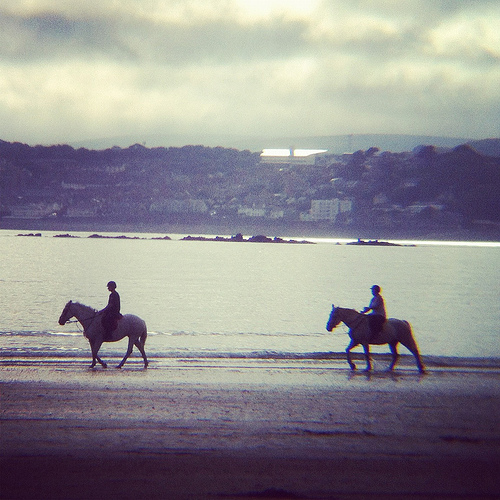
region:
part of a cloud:
[255, 29, 297, 74]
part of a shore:
[226, 365, 284, 423]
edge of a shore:
[228, 362, 286, 431]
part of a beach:
[191, 336, 271, 403]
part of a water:
[219, 290, 258, 322]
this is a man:
[366, 277, 384, 326]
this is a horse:
[121, 315, 141, 357]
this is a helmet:
[370, 282, 386, 294]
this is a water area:
[161, 244, 277, 321]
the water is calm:
[180, 266, 235, 321]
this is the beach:
[193, 374, 367, 491]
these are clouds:
[183, 24, 469, 123]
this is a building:
[261, 148, 314, 159]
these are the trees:
[421, 144, 469, 191]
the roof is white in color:
[266, 147, 293, 157]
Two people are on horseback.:
[55, 272, 451, 396]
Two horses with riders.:
[38, 270, 453, 396]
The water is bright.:
[166, 254, 283, 303]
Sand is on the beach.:
[190, 408, 353, 474]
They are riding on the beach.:
[49, 270, 459, 436]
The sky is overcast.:
[96, 63, 299, 123]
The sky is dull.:
[89, 57, 311, 126]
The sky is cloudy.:
[78, 58, 340, 123]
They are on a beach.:
[51, 270, 466, 432]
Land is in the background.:
[0, 129, 499, 281]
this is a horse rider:
[55, 280, 160, 364]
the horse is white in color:
[128, 317, 143, 339]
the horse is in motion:
[347, 323, 415, 377]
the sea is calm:
[201, 275, 292, 350]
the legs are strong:
[89, 344, 149, 369]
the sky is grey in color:
[204, 27, 351, 104]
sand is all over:
[149, 378, 331, 471]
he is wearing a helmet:
[106, 277, 116, 287]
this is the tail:
[138, 331, 151, 342]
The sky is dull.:
[76, 10, 378, 105]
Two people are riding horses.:
[50, 264, 463, 404]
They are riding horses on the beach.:
[51, 269, 451, 413]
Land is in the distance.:
[0, 125, 499, 264]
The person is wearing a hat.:
[354, 279, 389, 298]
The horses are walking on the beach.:
[43, 264, 445, 419]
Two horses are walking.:
[43, 265, 468, 412]